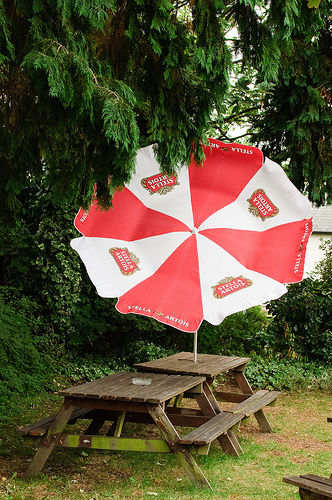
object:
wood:
[53, 432, 173, 455]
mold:
[72, 438, 167, 451]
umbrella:
[69, 136, 314, 363]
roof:
[187, 2, 331, 234]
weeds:
[0, 361, 60, 418]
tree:
[0, 0, 231, 280]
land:
[0, 365, 331, 498]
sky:
[145, 0, 281, 38]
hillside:
[0, 190, 166, 378]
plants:
[0, 196, 331, 427]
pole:
[191, 324, 197, 363]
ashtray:
[130, 376, 153, 388]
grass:
[0, 373, 331, 500]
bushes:
[2, 175, 292, 391]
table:
[134, 338, 272, 449]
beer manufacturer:
[245, 189, 276, 222]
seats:
[180, 389, 280, 456]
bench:
[280, 471, 331, 500]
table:
[19, 372, 240, 495]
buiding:
[191, 8, 331, 290]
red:
[199, 153, 228, 202]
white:
[199, 248, 227, 276]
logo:
[211, 273, 252, 303]